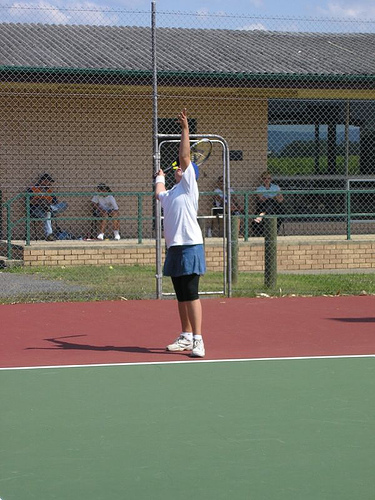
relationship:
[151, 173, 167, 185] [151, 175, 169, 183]
sweatband on wrist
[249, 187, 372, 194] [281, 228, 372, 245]
green handrail on deck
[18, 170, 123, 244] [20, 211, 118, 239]
people on chairs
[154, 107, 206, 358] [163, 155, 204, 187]
person has head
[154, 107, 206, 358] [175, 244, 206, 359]
person has leg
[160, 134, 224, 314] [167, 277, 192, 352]
person has leg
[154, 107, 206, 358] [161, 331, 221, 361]
person has feet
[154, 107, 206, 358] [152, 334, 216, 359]
person has feet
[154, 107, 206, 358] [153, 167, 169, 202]
person has arm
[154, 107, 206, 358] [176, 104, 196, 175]
person has arm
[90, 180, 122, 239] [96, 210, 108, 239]
person has leg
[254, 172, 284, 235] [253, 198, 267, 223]
person has leg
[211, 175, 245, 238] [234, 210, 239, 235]
person has leg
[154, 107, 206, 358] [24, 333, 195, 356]
person casting shadow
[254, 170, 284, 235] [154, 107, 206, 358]
person watching person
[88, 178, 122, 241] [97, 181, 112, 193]
child has ponytail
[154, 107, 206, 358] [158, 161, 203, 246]
person wearing t-shirt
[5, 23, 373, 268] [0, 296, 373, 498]
building next to court